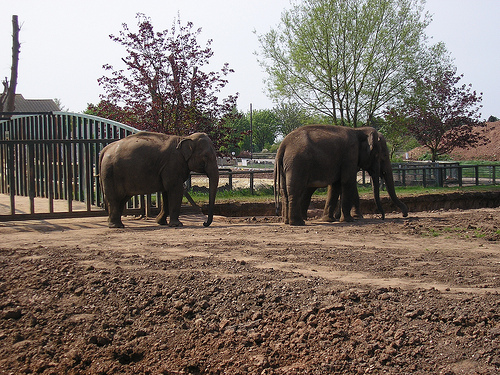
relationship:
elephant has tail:
[272, 126, 385, 225] [271, 155, 280, 209]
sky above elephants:
[60, 12, 416, 174] [84, 118, 410, 231]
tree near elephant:
[86, 6, 242, 133] [97, 131, 220, 228]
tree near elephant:
[254, 2, 456, 168] [270, 121, 409, 227]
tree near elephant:
[383, 65, 495, 167] [270, 121, 409, 227]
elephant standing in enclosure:
[272, 126, 385, 225] [0, 189, 497, 374]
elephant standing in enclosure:
[322, 132, 406, 219] [0, 189, 497, 374]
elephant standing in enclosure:
[97, 131, 220, 228] [0, 189, 497, 374]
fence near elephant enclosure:
[0, 110, 169, 219] [6, 78, 497, 364]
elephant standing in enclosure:
[97, 131, 220, 228] [3, 113, 496, 370]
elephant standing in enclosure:
[272, 126, 385, 225] [72, 166, 438, 341]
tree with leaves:
[254, 2, 498, 181] [154, 7, 219, 84]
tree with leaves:
[254, 2, 456, 168] [251, 1, 458, 147]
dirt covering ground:
[1, 204, 498, 372] [170, 262, 367, 324]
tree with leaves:
[383, 65, 495, 174] [380, 64, 496, 151]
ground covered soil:
[252, 285, 385, 366] [0, 199, 500, 374]